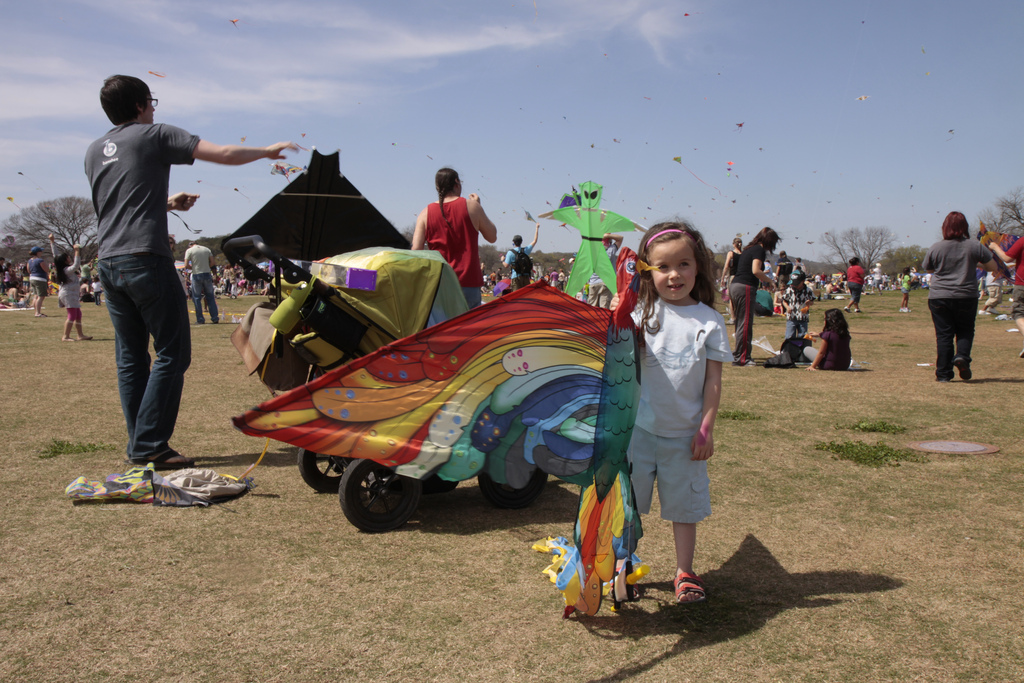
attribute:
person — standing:
[498, 232, 538, 286]